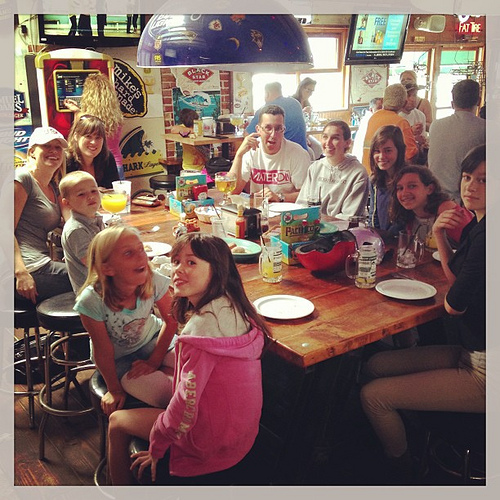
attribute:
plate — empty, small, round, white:
[377, 282, 438, 305]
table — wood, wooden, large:
[357, 318, 395, 330]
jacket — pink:
[181, 346, 279, 407]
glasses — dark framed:
[265, 122, 286, 144]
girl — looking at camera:
[154, 236, 285, 441]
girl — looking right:
[84, 234, 181, 402]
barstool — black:
[47, 297, 96, 355]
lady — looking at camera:
[363, 130, 406, 222]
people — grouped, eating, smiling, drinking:
[21, 114, 499, 414]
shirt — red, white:
[243, 136, 311, 191]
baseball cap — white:
[16, 121, 98, 146]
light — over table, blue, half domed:
[121, 9, 330, 84]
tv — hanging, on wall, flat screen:
[346, 18, 420, 67]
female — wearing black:
[423, 153, 499, 439]